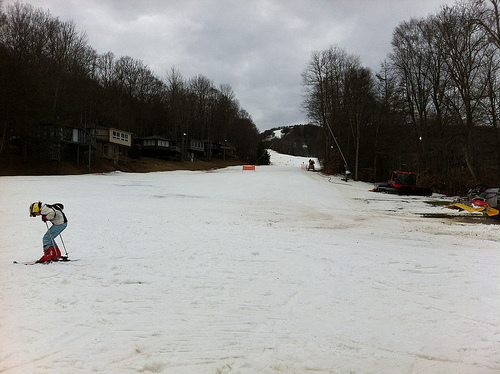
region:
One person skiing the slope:
[3, 173, 89, 285]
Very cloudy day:
[125, 34, 346, 174]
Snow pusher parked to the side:
[357, 159, 439, 199]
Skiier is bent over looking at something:
[11, 181, 79, 281]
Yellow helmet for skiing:
[24, 192, 43, 218]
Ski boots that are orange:
[35, 234, 65, 264]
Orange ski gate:
[234, 161, 268, 182]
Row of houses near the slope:
[21, 120, 213, 169]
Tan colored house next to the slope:
[87, 118, 136, 170]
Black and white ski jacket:
[42, 203, 71, 229]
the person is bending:
[25, 196, 102, 280]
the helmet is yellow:
[18, 199, 43, 219]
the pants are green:
[43, 220, 85, 247]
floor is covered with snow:
[215, 204, 340, 350]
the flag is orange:
[236, 164, 268, 186]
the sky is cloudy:
[185, 24, 327, 93]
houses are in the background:
[97, 123, 241, 163]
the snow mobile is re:
[361, 161, 458, 231]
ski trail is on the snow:
[183, 217, 315, 317]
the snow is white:
[194, 227, 346, 324]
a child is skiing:
[2, 161, 107, 297]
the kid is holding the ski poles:
[7, 160, 100, 277]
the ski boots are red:
[22, 242, 67, 264]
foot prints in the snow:
[90, 230, 240, 320]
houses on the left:
[37, 104, 227, 171]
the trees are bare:
[383, 17, 491, 125]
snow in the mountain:
[247, 113, 299, 144]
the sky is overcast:
[107, 13, 362, 78]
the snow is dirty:
[263, 197, 370, 248]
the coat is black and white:
[35, 197, 70, 231]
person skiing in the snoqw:
[18, 193, 72, 265]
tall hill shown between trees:
[255, 114, 327, 165]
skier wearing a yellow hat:
[25, 198, 66, 265]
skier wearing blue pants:
[22, 202, 69, 263]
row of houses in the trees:
[16, 123, 251, 165]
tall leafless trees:
[311, 14, 493, 186]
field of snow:
[31, 156, 483, 363]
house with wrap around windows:
[141, 137, 172, 151]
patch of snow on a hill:
[264, 121, 287, 143]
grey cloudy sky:
[38, 2, 439, 134]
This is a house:
[30, 110, 100, 159]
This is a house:
[84, 113, 140, 148]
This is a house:
[130, 123, 181, 160]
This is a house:
[174, 129, 208, 158]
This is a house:
[205, 130, 245, 160]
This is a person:
[26, 190, 81, 283]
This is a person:
[294, 150, 326, 181]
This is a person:
[336, 163, 353, 192]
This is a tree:
[348, 70, 367, 192]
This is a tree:
[404, 52, 441, 201]